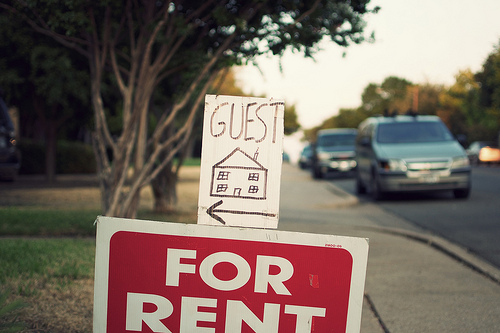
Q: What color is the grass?
A: Green.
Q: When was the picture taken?
A: Daytime.